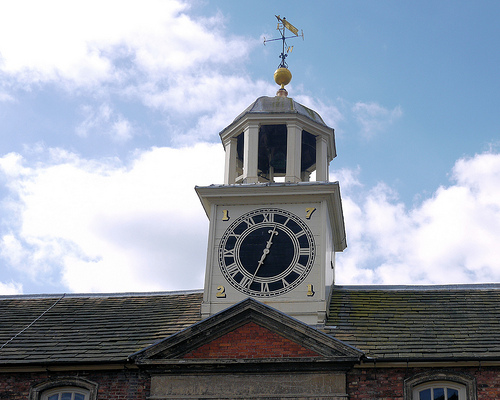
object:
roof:
[0, 283, 499, 365]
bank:
[0, 16, 500, 400]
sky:
[0, 0, 500, 234]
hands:
[266, 226, 278, 246]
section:
[17, 289, 113, 348]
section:
[45, 325, 144, 356]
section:
[447, 271, 481, 323]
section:
[458, 321, 497, 357]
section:
[334, 293, 373, 326]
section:
[337, 326, 375, 350]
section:
[130, 294, 177, 312]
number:
[244, 217, 256, 228]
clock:
[216, 206, 314, 298]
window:
[410, 379, 466, 399]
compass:
[261, 14, 304, 97]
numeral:
[262, 213, 274, 223]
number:
[220, 210, 230, 221]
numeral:
[227, 230, 241, 240]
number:
[306, 284, 314, 296]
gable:
[0, 291, 379, 366]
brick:
[177, 321, 322, 366]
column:
[285, 123, 302, 182]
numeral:
[283, 218, 290, 226]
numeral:
[294, 230, 305, 239]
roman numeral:
[300, 247, 311, 255]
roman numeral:
[292, 262, 306, 274]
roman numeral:
[260, 283, 269, 292]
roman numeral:
[239, 277, 251, 289]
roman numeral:
[226, 262, 240, 278]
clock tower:
[195, 14, 347, 326]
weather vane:
[262, 14, 306, 45]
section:
[374, 298, 425, 341]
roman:
[281, 278, 289, 288]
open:
[218, 95, 337, 183]